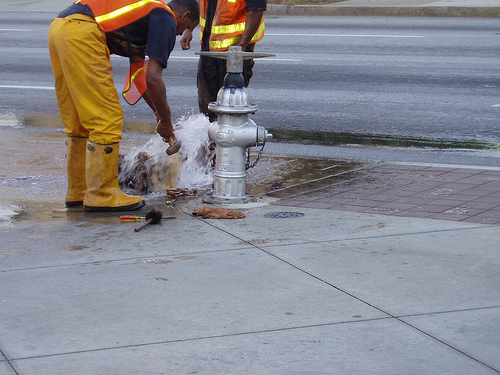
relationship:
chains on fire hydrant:
[242, 139, 270, 176] [199, 42, 275, 206]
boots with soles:
[80, 139, 147, 215] [63, 199, 145, 214]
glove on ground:
[185, 200, 242, 232] [1, 132, 496, 372]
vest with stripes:
[200, 0, 265, 47] [197, 12, 262, 47]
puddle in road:
[268, 124, 488, 154] [248, 12, 497, 137]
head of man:
[167, 0, 203, 37] [46, 0, 200, 213]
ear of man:
[171, 9, 202, 24] [46, 0, 200, 213]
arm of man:
[138, 57, 184, 160] [46, 0, 200, 213]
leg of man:
[46, 24, 89, 209] [46, 0, 200, 213]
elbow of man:
[131, 67, 179, 97] [44, 0, 224, 221]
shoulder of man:
[150, 4, 179, 31] [46, 0, 200, 213]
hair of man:
[173, 0, 200, 31] [46, 0, 200, 213]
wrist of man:
[159, 109, 172, 126] [46, 0, 200, 213]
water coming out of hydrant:
[116, 109, 211, 197] [191, 63, 297, 224]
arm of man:
[138, 27, 172, 119] [46, 0, 200, 213]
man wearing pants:
[46, 0, 200, 213] [29, 10, 116, 159]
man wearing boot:
[46, 0, 200, 213] [80, 132, 153, 217]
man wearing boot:
[46, 0, 200, 213] [51, 125, 92, 209]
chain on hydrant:
[242, 126, 284, 168] [172, 61, 300, 199]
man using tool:
[33, 7, 232, 225] [163, 133, 181, 157]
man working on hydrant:
[177, 2, 271, 118] [38, 0, 263, 215]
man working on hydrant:
[46, 0, 200, 213] [38, 0, 263, 215]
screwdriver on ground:
[116, 213, 177, 222] [1, 132, 496, 372]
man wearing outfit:
[46, 0, 200, 213] [75, 0, 178, 107]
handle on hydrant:
[196, 44, 276, 72] [206, 72, 272, 202]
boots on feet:
[74, 120, 185, 224] [62, 185, 143, 211]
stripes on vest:
[191, 11, 271, 54] [197, 3, 264, 55]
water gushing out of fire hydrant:
[116, 109, 211, 197] [207, 80, 272, 212]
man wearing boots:
[46, 0, 200, 213] [80, 139, 147, 215]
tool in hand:
[155, 121, 197, 173] [155, 121, 174, 137]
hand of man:
[147, 110, 180, 146] [46, 3, 183, 213]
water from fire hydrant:
[106, 108, 268, 205] [201, 47, 244, 227]